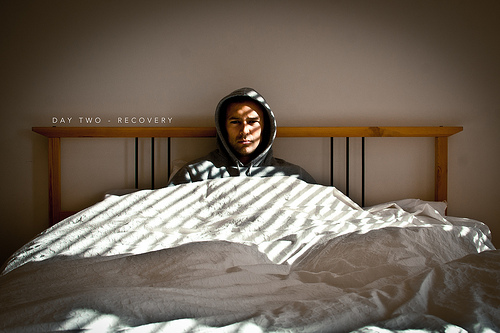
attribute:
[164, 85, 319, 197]
man — troubled, in grey, sitting up, serious, sitting, furrowing brow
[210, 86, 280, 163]
hood — grey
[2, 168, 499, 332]
bedding — fabric, shaded, lit, wrinkled, grey, white, striped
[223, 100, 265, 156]
face — in shadow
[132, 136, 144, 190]
pole — black, metal, thin, casting a shadow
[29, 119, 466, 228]
headboard — wooden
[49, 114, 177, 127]
words — displayed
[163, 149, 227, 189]
shoulder — in shadow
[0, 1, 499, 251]
wall — dark, grey, tan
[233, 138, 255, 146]
lips — closed